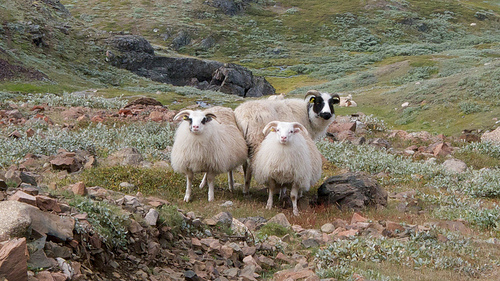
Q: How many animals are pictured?
A: Three.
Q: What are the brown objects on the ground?
A: Rocks.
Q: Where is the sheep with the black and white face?
A: In the back.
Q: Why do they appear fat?
A: Long thick wool.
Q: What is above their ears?
A: Horns.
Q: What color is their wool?
A: White.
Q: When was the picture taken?
A: During the daytime.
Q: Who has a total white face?
A: Sheep on right front.